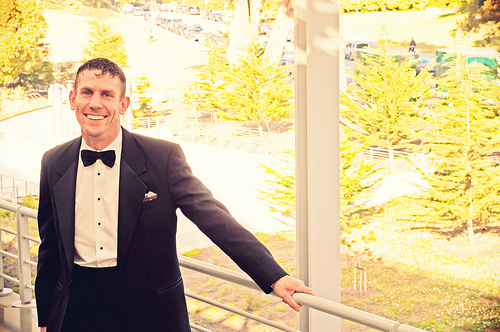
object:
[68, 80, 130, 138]
face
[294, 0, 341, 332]
gray pole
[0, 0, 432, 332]
building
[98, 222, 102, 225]
button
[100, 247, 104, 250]
button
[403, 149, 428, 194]
ground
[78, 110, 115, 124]
mouth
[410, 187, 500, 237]
trees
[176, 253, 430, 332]
handrail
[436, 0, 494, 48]
tree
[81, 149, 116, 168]
tie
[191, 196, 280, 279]
arm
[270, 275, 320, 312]
hand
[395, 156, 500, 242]
evergreen tree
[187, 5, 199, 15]
vehicle?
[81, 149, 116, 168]
black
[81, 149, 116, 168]
bow tie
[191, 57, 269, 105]
tree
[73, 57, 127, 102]
hair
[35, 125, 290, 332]
men's suit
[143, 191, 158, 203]
hankerchief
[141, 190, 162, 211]
pocket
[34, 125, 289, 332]
suit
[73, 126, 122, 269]
shirt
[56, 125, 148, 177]
collar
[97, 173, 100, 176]
black button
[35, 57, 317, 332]
man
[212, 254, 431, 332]
rail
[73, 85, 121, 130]
smile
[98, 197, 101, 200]
button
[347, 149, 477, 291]
background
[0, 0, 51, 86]
tree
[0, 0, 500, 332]
window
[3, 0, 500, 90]
background